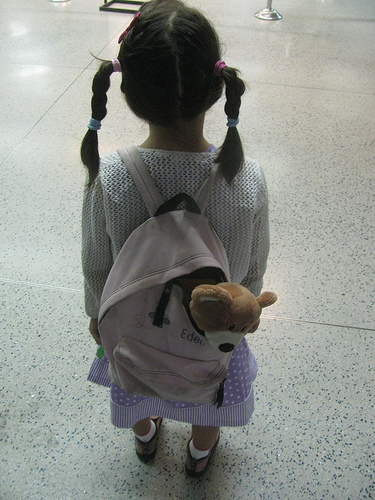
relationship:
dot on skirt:
[232, 372, 240, 380] [83, 333, 259, 428]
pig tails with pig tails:
[214, 64, 246, 181] [80, 57, 121, 185]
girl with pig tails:
[77, 2, 282, 478] [214, 64, 246, 181]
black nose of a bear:
[218, 342, 235, 353] [190, 281, 277, 351]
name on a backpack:
[176, 323, 211, 350] [94, 137, 250, 409]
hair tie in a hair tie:
[214, 58, 227, 78] [227, 116, 239, 126]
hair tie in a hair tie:
[214, 58, 227, 78] [109, 58, 123, 71]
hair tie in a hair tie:
[214, 58, 227, 78] [86, 116, 100, 131]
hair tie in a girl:
[214, 58, 227, 78] [77, 2, 282, 478]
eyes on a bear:
[224, 314, 254, 340] [169, 267, 282, 374]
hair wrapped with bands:
[74, 0, 253, 198] [213, 55, 241, 131]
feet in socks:
[116, 366, 241, 484] [129, 415, 212, 461]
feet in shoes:
[116, 366, 241, 484] [120, 406, 232, 487]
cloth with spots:
[119, 352, 277, 418] [229, 357, 246, 403]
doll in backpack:
[189, 281, 278, 354] [96, 207, 231, 403]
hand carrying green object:
[79, 302, 99, 338] [87, 345, 112, 366]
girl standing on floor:
[77, 2, 282, 478] [0, 1, 363, 490]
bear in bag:
[189, 280, 278, 370] [80, 137, 250, 420]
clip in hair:
[118, 11, 139, 42] [74, 0, 253, 198]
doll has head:
[187, 280, 277, 352] [187, 280, 278, 353]